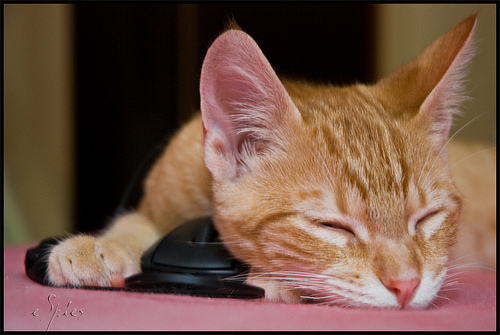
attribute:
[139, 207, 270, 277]
mouse — black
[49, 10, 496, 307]
cat — sleeping, brown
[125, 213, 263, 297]
mouse — black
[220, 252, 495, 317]
whiskers — white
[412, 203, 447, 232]
eye — closed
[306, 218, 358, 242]
eye — closed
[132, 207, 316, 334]
mouse — black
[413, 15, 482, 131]
ear — brown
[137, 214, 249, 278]
mouse — black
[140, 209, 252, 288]
mouse — computer mouse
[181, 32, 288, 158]
ear — pointy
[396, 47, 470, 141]
ear — pointy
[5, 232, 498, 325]
surface — pink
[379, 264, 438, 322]
nose — pink, white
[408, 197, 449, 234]
eye — closed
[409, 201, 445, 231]
eye — shut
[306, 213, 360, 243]
eye — closed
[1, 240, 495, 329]
pad — pink